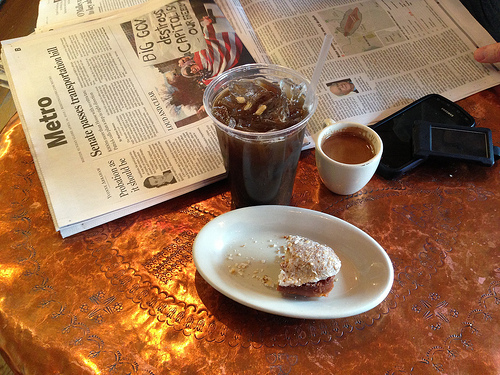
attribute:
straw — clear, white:
[302, 33, 335, 112]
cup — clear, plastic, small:
[204, 63, 316, 210]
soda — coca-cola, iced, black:
[214, 75, 304, 208]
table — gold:
[3, 4, 499, 374]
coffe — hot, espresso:
[321, 132, 378, 164]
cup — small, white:
[315, 116, 384, 195]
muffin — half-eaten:
[277, 234, 341, 298]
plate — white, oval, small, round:
[194, 204, 394, 321]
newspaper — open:
[4, 1, 499, 240]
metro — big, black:
[37, 97, 69, 149]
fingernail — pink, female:
[473, 43, 500, 65]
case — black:
[411, 119, 498, 168]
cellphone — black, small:
[367, 92, 476, 180]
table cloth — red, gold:
[2, 1, 497, 374]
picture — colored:
[113, 1, 264, 129]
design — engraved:
[8, 153, 500, 373]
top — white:
[278, 235, 341, 286]